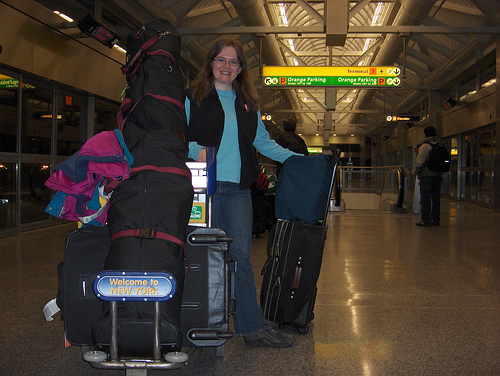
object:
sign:
[93, 270, 178, 301]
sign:
[260, 65, 402, 87]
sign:
[386, 115, 421, 122]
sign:
[80, 18, 123, 48]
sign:
[440, 101, 453, 111]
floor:
[0, 197, 495, 369]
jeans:
[208, 178, 271, 339]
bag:
[89, 18, 195, 359]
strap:
[129, 48, 186, 80]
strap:
[121, 93, 185, 132]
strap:
[130, 164, 192, 180]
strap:
[111, 227, 187, 259]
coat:
[42, 127, 128, 228]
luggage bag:
[259, 217, 328, 335]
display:
[91, 24, 117, 43]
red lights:
[95, 32, 104, 39]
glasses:
[212, 56, 241, 66]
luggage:
[53, 222, 237, 354]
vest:
[183, 82, 258, 192]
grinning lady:
[183, 39, 307, 350]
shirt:
[183, 84, 306, 189]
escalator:
[333, 162, 405, 211]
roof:
[53, 1, 496, 137]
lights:
[278, 3, 289, 27]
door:
[478, 129, 495, 200]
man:
[411, 124, 446, 225]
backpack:
[419, 141, 452, 172]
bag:
[272, 149, 335, 224]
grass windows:
[21, 79, 55, 157]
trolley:
[80, 270, 190, 373]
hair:
[183, 37, 258, 111]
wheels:
[297, 323, 309, 334]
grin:
[215, 67, 237, 77]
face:
[212, 46, 240, 81]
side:
[261, 217, 325, 327]